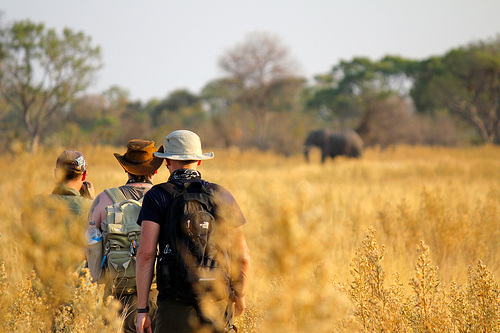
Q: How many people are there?
A: Three.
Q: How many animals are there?
A: One.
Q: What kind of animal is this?
A: Elephant.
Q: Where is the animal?
A: Near the trees.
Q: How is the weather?
A: Sunny.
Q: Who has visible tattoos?
A: The person in the middle.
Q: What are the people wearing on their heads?
A: Hats.